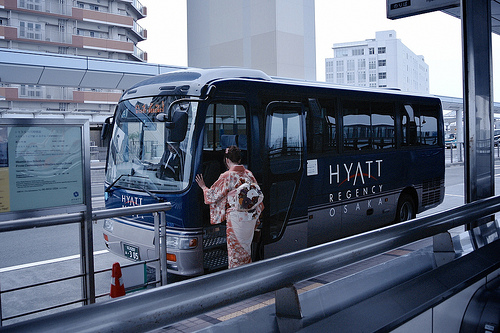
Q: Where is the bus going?
A: A Hyatt hotel.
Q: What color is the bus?
A: Blue.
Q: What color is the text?
A: White.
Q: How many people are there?
A: One.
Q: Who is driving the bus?
A: The woman.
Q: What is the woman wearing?
A: A kimono.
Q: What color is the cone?
A: Orange.